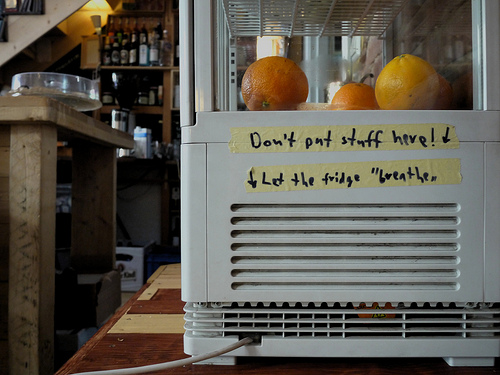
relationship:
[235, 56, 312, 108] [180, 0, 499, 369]
orange in a container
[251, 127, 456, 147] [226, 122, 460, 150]
print on a tape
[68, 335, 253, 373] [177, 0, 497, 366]
cord on refrigerator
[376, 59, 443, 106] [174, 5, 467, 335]
lemon in refrigerator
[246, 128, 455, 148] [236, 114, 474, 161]
letters on tape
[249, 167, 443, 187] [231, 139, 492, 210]
writing on tape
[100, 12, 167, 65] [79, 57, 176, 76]
bottles on shelf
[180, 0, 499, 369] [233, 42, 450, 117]
container full of oranges